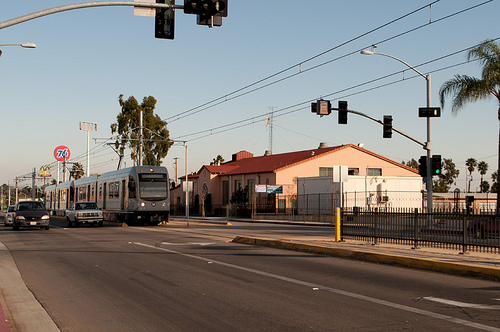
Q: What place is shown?
A: It is a street.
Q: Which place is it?
A: It is a street.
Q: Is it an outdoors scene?
A: Yes, it is outdoors.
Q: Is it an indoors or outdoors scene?
A: It is outdoors.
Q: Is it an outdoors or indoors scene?
A: It is outdoors.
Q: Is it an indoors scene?
A: No, it is outdoors.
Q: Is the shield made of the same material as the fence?
A: No, the shield is made of glass and the fence is made of metal.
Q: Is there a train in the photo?
A: Yes, there is a train.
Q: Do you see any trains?
A: Yes, there is a train.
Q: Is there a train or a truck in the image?
A: Yes, there is a train.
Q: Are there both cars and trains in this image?
A: Yes, there are both a train and a car.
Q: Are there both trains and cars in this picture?
A: Yes, there are both a train and a car.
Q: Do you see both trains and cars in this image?
A: Yes, there are both a train and a car.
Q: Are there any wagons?
A: No, there are no wagons.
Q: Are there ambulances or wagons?
A: No, there are no wagons or ambulances.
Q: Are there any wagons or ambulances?
A: No, there are no wagons or ambulances.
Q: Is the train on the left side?
A: Yes, the train is on the left of the image.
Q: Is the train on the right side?
A: No, the train is on the left of the image.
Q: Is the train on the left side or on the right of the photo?
A: The train is on the left of the image.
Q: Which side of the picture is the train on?
A: The train is on the left of the image.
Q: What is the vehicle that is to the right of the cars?
A: The vehicle is a train.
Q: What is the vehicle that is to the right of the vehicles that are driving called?
A: The vehicle is a train.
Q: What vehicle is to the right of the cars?
A: The vehicle is a train.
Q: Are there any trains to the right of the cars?
A: Yes, there is a train to the right of the cars.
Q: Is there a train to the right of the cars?
A: Yes, there is a train to the right of the cars.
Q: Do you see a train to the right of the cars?
A: Yes, there is a train to the right of the cars.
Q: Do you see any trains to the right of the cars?
A: Yes, there is a train to the right of the cars.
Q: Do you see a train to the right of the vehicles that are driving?
A: Yes, there is a train to the right of the cars.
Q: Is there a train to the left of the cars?
A: No, the train is to the right of the cars.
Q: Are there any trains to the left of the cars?
A: No, the train is to the right of the cars.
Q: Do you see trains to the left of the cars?
A: No, the train is to the right of the cars.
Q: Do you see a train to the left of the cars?
A: No, the train is to the right of the cars.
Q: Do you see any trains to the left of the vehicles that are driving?
A: No, the train is to the right of the cars.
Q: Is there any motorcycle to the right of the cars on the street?
A: No, there is a train to the right of the cars.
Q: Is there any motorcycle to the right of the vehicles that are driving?
A: No, there is a train to the right of the cars.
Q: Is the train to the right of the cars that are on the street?
A: Yes, the train is to the right of the cars.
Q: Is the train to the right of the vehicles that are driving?
A: Yes, the train is to the right of the cars.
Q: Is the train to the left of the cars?
A: No, the train is to the right of the cars.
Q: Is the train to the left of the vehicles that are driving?
A: No, the train is to the right of the cars.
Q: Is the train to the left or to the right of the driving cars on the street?
A: The train is to the right of the cars.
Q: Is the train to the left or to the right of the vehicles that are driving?
A: The train is to the right of the cars.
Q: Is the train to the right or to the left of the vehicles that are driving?
A: The train is to the right of the cars.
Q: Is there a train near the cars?
A: Yes, there is a train near the cars.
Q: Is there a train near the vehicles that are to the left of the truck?
A: Yes, there is a train near the cars.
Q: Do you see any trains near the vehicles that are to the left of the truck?
A: Yes, there is a train near the cars.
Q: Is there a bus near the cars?
A: No, there is a train near the cars.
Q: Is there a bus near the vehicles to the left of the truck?
A: No, there is a train near the cars.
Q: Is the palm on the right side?
A: Yes, the palm is on the right of the image.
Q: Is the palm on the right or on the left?
A: The palm is on the right of the image.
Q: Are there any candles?
A: No, there are no candles.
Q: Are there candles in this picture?
A: No, there are no candles.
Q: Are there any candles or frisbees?
A: No, there are no candles or frisbees.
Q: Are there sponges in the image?
A: No, there are no sponges.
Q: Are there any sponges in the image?
A: No, there are no sponges.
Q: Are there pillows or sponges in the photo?
A: No, there are no sponges or pillows.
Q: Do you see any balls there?
A: No, there are no balls.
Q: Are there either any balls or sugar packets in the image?
A: No, there are no balls or sugar packets.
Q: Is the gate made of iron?
A: Yes, the gate is made of iron.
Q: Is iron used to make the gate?
A: Yes, the gate is made of iron.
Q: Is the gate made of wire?
A: No, the gate is made of iron.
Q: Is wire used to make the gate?
A: No, the gate is made of iron.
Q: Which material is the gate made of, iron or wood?
A: The gate is made of iron.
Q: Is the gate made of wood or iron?
A: The gate is made of iron.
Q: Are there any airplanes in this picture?
A: No, there are no airplanes.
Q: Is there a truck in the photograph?
A: Yes, there is a truck.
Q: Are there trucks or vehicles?
A: Yes, there is a truck.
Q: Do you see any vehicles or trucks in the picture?
A: Yes, there is a truck.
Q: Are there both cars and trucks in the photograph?
A: Yes, there are both a truck and cars.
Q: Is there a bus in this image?
A: No, there are no buses.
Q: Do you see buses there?
A: No, there are no buses.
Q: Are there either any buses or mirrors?
A: No, there are no buses or mirrors.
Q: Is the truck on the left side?
A: Yes, the truck is on the left of the image.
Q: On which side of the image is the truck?
A: The truck is on the left of the image.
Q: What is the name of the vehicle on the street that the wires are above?
A: The vehicle is a truck.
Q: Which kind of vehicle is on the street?
A: The vehicle is a truck.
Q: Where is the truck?
A: The truck is on the street.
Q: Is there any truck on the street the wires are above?
A: Yes, there is a truck on the street.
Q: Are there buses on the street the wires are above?
A: No, there is a truck on the street.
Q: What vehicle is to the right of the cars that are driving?
A: The vehicle is a truck.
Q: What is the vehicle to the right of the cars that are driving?
A: The vehicle is a truck.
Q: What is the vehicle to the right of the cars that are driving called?
A: The vehicle is a truck.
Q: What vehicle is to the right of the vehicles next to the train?
A: The vehicle is a truck.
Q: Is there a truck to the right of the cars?
A: Yes, there is a truck to the right of the cars.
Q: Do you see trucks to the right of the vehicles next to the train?
A: Yes, there is a truck to the right of the cars.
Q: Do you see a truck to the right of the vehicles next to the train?
A: Yes, there is a truck to the right of the cars.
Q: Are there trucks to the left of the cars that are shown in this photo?
A: No, the truck is to the right of the cars.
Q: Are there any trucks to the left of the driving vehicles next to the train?
A: No, the truck is to the right of the cars.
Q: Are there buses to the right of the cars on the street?
A: No, there is a truck to the right of the cars.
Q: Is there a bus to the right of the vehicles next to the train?
A: No, there is a truck to the right of the cars.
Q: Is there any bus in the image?
A: No, there are no buses.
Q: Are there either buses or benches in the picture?
A: No, there are no buses or benches.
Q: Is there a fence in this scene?
A: Yes, there is a fence.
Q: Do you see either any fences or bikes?
A: Yes, there is a fence.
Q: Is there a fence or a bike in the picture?
A: Yes, there is a fence.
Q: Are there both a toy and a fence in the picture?
A: No, there is a fence but no toys.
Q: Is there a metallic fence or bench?
A: Yes, there is a metal fence.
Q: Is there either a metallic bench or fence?
A: Yes, there is a metal fence.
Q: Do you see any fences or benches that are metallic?
A: Yes, the fence is metallic.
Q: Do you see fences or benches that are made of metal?
A: Yes, the fence is made of metal.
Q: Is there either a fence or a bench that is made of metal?
A: Yes, the fence is made of metal.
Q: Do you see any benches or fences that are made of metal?
A: Yes, the fence is made of metal.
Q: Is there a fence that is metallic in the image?
A: Yes, there is a metal fence.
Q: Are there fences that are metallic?
A: Yes, there is a fence that is metallic.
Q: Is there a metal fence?
A: Yes, there is a fence that is made of metal.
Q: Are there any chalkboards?
A: No, there are no chalkboards.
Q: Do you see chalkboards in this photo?
A: No, there are no chalkboards.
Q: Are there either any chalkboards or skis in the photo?
A: No, there are no chalkboards or skis.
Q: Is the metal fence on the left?
A: No, the fence is on the right of the image.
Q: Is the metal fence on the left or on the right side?
A: The fence is on the right of the image.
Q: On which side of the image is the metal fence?
A: The fence is on the right of the image.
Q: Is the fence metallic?
A: Yes, the fence is metallic.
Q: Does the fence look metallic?
A: Yes, the fence is metallic.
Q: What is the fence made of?
A: The fence is made of metal.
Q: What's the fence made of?
A: The fence is made of metal.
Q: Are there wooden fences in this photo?
A: No, there is a fence but it is metallic.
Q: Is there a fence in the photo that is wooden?
A: No, there is a fence but it is metallic.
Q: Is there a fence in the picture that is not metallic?
A: No, there is a fence but it is metallic.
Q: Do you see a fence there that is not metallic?
A: No, there is a fence but it is metallic.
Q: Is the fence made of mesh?
A: No, the fence is made of metal.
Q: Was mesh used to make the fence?
A: No, the fence is made of metal.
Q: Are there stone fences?
A: No, there is a fence but it is made of metal.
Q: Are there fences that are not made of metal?
A: No, there is a fence but it is made of metal.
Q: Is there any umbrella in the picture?
A: No, there are no umbrellas.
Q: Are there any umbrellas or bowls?
A: No, there are no umbrellas or bowls.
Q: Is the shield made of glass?
A: Yes, the shield is made of glass.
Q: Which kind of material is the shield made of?
A: The shield is made of glass.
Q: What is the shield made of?
A: The shield is made of glass.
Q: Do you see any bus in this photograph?
A: No, there are no buses.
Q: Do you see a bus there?
A: No, there are no buses.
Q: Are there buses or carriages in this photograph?
A: No, there are no buses or carriages.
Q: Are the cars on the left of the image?
A: Yes, the cars are on the left of the image.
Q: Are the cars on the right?
A: No, the cars are on the left of the image.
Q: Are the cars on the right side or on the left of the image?
A: The cars are on the left of the image.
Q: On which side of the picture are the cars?
A: The cars are on the left of the image.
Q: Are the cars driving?
A: Yes, the cars are driving.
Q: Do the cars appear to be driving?
A: Yes, the cars are driving.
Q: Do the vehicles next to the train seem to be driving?
A: Yes, the cars are driving.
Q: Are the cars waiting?
A: No, the cars are driving.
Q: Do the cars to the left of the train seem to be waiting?
A: No, the cars are driving.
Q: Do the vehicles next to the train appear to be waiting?
A: No, the cars are driving.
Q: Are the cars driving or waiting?
A: The cars are driving.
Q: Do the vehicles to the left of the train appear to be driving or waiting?
A: The cars are driving.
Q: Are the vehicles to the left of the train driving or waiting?
A: The cars are driving.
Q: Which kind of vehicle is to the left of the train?
A: The vehicles are cars.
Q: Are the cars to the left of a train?
A: Yes, the cars are to the left of a train.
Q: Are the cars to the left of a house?
A: No, the cars are to the left of a train.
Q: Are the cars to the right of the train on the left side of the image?
A: No, the cars are to the left of the train.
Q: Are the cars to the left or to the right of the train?
A: The cars are to the left of the train.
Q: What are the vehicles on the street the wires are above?
A: The vehicles are cars.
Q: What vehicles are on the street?
A: The vehicles are cars.